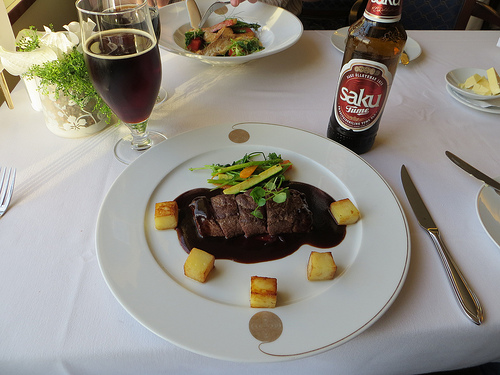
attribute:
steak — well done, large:
[194, 186, 314, 238]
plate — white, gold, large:
[97, 125, 412, 365]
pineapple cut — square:
[250, 275, 280, 307]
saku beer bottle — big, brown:
[327, 0, 408, 154]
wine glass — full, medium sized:
[74, 1, 167, 164]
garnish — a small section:
[189, 150, 292, 218]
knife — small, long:
[401, 163, 485, 325]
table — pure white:
[1, 31, 500, 375]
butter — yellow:
[464, 68, 497, 94]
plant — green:
[21, 24, 110, 120]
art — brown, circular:
[249, 312, 284, 343]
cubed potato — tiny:
[155, 201, 178, 230]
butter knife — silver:
[445, 150, 499, 193]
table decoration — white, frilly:
[5, 17, 93, 77]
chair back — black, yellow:
[402, 0, 465, 30]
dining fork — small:
[200, 1, 230, 28]